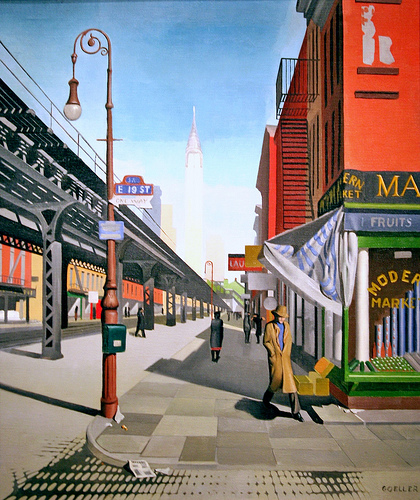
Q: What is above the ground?
A: Train tracks.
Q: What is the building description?
A: Red brick.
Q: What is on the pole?
A: Street light.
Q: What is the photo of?
A: A painting.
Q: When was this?
A: Daytime.